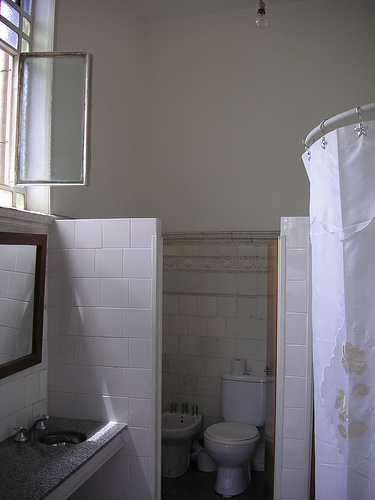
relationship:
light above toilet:
[250, 2, 272, 35] [204, 358, 266, 496]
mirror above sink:
[1, 235, 51, 376] [3, 410, 121, 500]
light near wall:
[250, 2, 272, 35] [50, 4, 373, 475]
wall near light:
[50, 4, 373, 475] [250, 2, 272, 35]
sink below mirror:
[3, 410, 121, 500] [1, 235, 51, 376]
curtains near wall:
[307, 104, 371, 496] [50, 4, 373, 475]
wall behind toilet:
[50, 4, 373, 475] [204, 358, 266, 496]